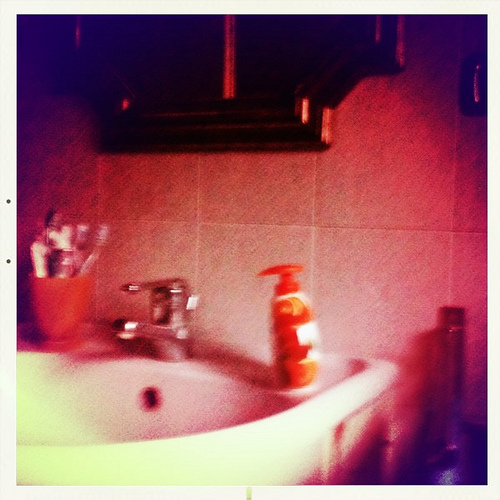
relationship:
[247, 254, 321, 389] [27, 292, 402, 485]
bottle on sink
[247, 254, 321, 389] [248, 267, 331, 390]
bottle of soap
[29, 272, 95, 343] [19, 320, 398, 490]
cup on wash basin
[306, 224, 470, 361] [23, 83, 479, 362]
tile on wall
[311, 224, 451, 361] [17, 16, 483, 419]
tile on wall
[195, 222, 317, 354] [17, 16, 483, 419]
tile on wall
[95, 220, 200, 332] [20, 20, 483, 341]
tile on wall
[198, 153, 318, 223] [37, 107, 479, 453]
tile on wall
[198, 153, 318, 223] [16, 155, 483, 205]
tile on wall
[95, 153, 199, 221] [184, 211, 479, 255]
tile on wall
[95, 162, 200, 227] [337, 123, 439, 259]
tile on wall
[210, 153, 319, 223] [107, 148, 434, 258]
tile on wall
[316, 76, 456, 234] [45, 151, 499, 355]
white tile on wall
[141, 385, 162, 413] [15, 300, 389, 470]
drain hole at back of sink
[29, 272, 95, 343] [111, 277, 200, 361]
cup to left of bathroom faucet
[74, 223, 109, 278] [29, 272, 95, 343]
toothbrush in cup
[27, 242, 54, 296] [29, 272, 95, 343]
toothpaste in cup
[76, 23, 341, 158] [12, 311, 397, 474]
mirror above sink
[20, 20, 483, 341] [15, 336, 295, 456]
wall above sink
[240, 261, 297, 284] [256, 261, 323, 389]
spout of dispenser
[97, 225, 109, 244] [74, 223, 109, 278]
bristles of toothbrush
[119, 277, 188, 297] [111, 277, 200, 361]
handle of bathroom faucet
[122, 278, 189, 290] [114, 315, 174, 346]
handle of faucet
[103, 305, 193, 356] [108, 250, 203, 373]
spout of bathroom faucet